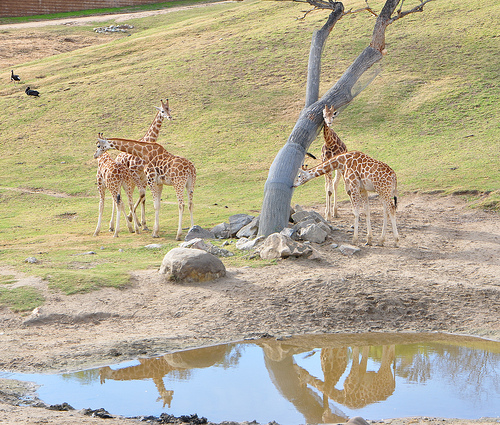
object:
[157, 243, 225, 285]
rock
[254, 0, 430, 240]
tree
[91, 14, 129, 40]
plant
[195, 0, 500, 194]
hill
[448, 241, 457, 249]
patch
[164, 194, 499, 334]
dirt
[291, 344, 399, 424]
reflection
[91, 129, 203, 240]
giraffe's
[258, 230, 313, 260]
rocks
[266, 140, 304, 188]
section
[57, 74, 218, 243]
three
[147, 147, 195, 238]
standing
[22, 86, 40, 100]
birds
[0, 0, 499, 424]
background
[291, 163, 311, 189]
head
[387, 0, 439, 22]
branches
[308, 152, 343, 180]
neck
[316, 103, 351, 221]
giraffes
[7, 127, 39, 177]
left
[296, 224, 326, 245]
stone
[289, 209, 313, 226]
stones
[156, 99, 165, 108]
horns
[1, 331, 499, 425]
waterhole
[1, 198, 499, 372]
sand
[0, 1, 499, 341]
ground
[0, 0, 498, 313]
grass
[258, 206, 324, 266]
pile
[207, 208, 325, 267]
circle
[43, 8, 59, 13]
red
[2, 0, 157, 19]
wall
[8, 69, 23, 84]
ostrich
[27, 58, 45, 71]
distance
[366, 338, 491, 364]
grasses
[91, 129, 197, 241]
big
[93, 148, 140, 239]
smaller giraffe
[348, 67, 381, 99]
wire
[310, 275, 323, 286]
footprints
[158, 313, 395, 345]
shoreline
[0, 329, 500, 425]
pond